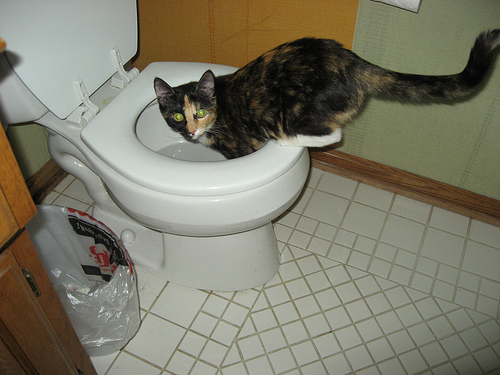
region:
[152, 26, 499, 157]
a cat perched on a toilet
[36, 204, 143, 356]
a plastic bag on a wastebasket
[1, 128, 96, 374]
wooden cabinet in a bathroom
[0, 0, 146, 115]
a white toilet seat cover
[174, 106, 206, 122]
green eyes of a cat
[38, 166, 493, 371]
white tiles on the floor of a bathroom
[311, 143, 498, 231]
wooden baseboard in a bathroom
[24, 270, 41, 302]
a golden hinge on a cabinet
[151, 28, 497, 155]
a tabby cat on a toilet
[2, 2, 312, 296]
a white toilet with its seat up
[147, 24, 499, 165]
A calico cat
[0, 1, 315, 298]
A white porcelain toilet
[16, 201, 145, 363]
A small trash can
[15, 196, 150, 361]
A plastic bag in a can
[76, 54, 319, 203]
A white toilet seat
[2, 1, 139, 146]
On open, white toilet seat lid.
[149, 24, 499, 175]
A cat with its front feet in a toilet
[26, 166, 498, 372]
A white tile floor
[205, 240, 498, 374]
White tiles going diagonal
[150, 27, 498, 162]
A cat looking at the camera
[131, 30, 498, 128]
this is a cat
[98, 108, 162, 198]
this is a toilet sink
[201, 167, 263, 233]
the sink is white in color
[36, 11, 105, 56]
this is the lid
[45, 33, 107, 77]
the lid is white in color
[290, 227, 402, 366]
this is the floor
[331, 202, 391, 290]
the floor is white in color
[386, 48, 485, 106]
this is the tail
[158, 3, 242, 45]
this is the wall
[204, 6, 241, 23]
the wall is brown in color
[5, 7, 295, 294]
A white porcelain toilet.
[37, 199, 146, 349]
A trash can on floor.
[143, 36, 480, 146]
A cat on a toilet.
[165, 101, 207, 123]
Green eyes on a cat.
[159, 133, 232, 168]
Water inside a toilet.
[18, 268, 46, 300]
A hinge on a cabinet.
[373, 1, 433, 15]
A roll of toilet paper.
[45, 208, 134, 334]
A plastic shopping bag in trash can.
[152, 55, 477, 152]
A black and brown calico cat.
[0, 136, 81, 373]
A brown wooden cabinet.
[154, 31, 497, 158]
A cat stepping on a toilet seat.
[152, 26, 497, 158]
A cat looking at the camera.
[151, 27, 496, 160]
A cat with yellow eyes stepping on toilet seat.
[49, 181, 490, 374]
A tiled floor of a bathroom.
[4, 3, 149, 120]
Part of a toilet cover.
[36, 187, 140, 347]
Trash can in a corner of bathroom.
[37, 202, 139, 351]
Trash can with a polythene bag in it.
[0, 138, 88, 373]
Wooden cabinet in the corner of bathroom.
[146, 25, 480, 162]
A black and tan cat in a bathroom.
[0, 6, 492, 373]
A tidy bathroom with cat on top of toilet seat.